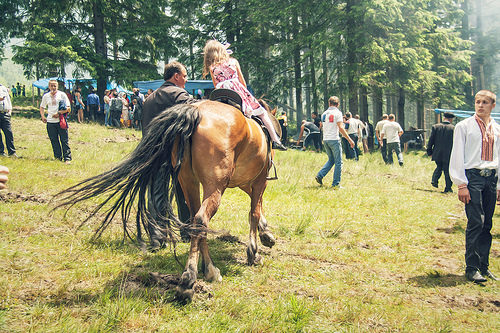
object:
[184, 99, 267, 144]
horse back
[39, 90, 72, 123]
ankara shirt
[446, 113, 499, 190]
luxury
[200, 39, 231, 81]
hair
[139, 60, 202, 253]
man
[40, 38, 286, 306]
riding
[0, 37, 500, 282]
crowd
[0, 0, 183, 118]
trees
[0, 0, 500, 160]
mist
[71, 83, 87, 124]
watching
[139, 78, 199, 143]
coat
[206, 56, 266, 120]
dress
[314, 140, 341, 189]
jeans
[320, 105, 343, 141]
shirt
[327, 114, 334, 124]
flag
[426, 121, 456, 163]
jacket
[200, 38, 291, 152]
girl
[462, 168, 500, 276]
pants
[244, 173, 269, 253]
legs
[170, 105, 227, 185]
behind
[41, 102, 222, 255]
long tail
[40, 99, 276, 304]
brown horse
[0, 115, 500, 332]
grass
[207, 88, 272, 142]
saddle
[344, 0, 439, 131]
pine trees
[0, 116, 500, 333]
field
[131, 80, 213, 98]
truck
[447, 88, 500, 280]
man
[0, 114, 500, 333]
floor